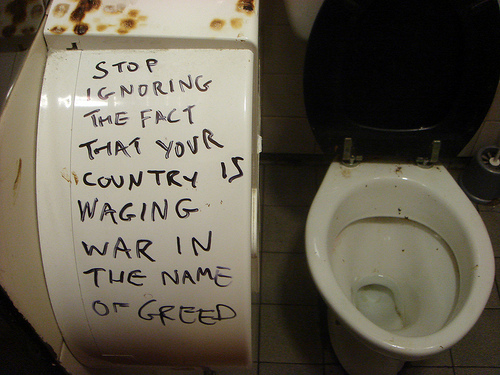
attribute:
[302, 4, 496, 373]
toilet — dirty, disgusting, black, white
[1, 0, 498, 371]
bathroom — dirty, nasty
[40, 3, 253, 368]
dispenser — white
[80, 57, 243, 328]
letters — black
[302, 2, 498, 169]
lid — black, up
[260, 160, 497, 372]
floor — gray, tile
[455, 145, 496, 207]
toilet brush — dirty